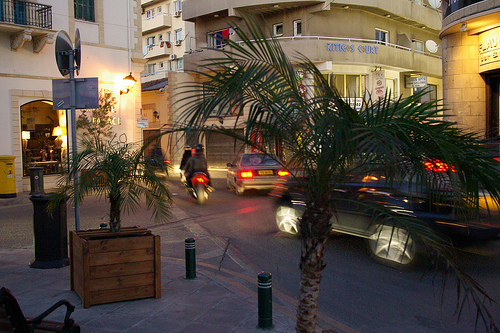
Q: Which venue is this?
A: This is a road.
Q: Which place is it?
A: It is a road.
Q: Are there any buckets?
A: No, there are no buckets.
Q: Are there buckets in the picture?
A: No, there are no buckets.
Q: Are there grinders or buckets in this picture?
A: No, there are no buckets or grinders.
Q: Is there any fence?
A: No, there are no fences.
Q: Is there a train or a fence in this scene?
A: No, there are no fences or trains.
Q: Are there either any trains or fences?
A: No, there are no fences or trains.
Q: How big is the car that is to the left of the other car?
A: The car is small.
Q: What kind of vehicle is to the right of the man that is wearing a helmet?
A: The vehicle is a car.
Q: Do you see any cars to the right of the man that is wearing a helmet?
A: Yes, there is a car to the right of the man.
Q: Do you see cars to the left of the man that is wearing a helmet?
A: No, the car is to the right of the man.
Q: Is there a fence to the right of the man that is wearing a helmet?
A: No, there is a car to the right of the man.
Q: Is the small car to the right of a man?
A: Yes, the car is to the right of a man.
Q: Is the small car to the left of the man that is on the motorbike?
A: No, the car is to the right of the man.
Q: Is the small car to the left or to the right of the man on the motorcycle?
A: The car is to the right of the man.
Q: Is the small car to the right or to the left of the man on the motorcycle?
A: The car is to the right of the man.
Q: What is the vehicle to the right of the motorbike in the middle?
A: The vehicle is a car.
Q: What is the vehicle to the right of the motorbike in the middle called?
A: The vehicle is a car.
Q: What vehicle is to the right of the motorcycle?
A: The vehicle is a car.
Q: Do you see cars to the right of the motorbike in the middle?
A: Yes, there is a car to the right of the motorcycle.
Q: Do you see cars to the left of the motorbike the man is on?
A: No, the car is to the right of the motorcycle.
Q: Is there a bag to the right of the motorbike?
A: No, there is a car to the right of the motorbike.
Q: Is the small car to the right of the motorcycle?
A: Yes, the car is to the right of the motorcycle.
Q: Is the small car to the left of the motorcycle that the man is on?
A: No, the car is to the right of the motorcycle.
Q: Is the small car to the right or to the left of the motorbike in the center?
A: The car is to the right of the motorcycle.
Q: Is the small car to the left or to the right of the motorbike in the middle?
A: The car is to the right of the motorcycle.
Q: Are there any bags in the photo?
A: No, there are no bags.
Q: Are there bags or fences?
A: No, there are no bags or fences.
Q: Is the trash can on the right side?
A: No, the trash can is on the left of the image.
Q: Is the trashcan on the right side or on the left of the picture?
A: The trashcan is on the left of the image.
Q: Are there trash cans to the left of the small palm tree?
A: Yes, there is a trash can to the left of the palm.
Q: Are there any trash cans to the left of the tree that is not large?
A: Yes, there is a trash can to the left of the palm.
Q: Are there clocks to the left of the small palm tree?
A: No, there is a trash can to the left of the palm tree.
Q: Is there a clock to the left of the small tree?
A: No, there is a trash can to the left of the palm tree.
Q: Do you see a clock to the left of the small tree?
A: No, there is a trash can to the left of the palm tree.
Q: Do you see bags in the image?
A: No, there are no bags.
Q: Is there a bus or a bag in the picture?
A: No, there are no bags or buses.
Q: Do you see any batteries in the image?
A: No, there are no batteries.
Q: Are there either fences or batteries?
A: No, there are no batteries or fences.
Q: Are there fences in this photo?
A: No, there are no fences.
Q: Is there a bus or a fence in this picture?
A: No, there are no fences or buses.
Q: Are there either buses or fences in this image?
A: No, there are no fences or buses.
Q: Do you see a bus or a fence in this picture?
A: No, there are no fences or buses.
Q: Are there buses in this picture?
A: No, there are no buses.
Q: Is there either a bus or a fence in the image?
A: No, there are no buses or fences.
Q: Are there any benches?
A: Yes, there is a bench.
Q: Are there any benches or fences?
A: Yes, there is a bench.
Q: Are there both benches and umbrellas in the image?
A: No, there is a bench but no umbrellas.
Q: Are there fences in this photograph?
A: No, there are no fences.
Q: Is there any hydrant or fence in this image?
A: No, there are no fences or fire hydrants.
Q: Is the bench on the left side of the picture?
A: Yes, the bench is on the left of the image.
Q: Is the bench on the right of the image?
A: No, the bench is on the left of the image.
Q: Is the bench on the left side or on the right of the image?
A: The bench is on the left of the image.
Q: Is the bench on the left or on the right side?
A: The bench is on the left of the image.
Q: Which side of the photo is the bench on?
A: The bench is on the left of the image.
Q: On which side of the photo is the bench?
A: The bench is on the left of the image.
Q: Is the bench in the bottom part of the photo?
A: Yes, the bench is in the bottom of the image.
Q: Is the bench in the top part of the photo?
A: No, the bench is in the bottom of the image.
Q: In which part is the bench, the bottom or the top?
A: The bench is in the bottom of the image.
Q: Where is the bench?
A: The bench is on the sidewalk.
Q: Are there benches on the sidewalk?
A: Yes, there is a bench on the sidewalk.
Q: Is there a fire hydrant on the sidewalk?
A: No, there is a bench on the sidewalk.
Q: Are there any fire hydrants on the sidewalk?
A: No, there is a bench on the sidewalk.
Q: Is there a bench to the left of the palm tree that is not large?
A: Yes, there is a bench to the left of the palm.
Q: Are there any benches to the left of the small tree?
A: Yes, there is a bench to the left of the palm.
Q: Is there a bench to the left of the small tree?
A: Yes, there is a bench to the left of the palm.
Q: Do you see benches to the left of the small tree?
A: Yes, there is a bench to the left of the palm.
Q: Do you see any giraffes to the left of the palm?
A: No, there is a bench to the left of the palm.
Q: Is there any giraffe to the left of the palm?
A: No, there is a bench to the left of the palm.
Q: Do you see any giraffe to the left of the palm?
A: No, there is a bench to the left of the palm.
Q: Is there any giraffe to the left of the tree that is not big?
A: No, there is a bench to the left of the palm.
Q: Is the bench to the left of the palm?
A: Yes, the bench is to the left of the palm.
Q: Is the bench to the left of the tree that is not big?
A: Yes, the bench is to the left of the palm.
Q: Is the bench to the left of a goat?
A: No, the bench is to the left of the palm.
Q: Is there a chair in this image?
A: No, there are no chairs.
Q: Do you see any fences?
A: No, there are no fences.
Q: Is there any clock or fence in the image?
A: No, there are no fences or clocks.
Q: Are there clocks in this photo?
A: No, there are no clocks.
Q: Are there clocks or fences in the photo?
A: No, there are no clocks or fences.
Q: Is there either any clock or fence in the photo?
A: No, there are no clocks or fences.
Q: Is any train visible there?
A: No, there are no trains.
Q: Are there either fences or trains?
A: No, there are no trains or fences.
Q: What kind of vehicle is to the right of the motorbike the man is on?
A: The vehicle is a car.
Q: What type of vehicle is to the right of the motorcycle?
A: The vehicle is a car.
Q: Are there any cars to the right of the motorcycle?
A: Yes, there is a car to the right of the motorcycle.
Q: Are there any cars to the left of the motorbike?
A: No, the car is to the right of the motorbike.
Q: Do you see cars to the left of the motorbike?
A: No, the car is to the right of the motorbike.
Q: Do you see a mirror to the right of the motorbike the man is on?
A: No, there is a car to the right of the motorcycle.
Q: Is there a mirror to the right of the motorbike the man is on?
A: No, there is a car to the right of the motorcycle.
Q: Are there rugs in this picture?
A: No, there are no rugs.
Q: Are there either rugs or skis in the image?
A: No, there are no rugs or skis.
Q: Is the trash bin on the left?
A: Yes, the trash bin is on the left of the image.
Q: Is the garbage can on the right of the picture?
A: No, the garbage can is on the left of the image.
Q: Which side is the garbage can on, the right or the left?
A: The garbage can is on the left of the image.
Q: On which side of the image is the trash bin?
A: The trash bin is on the left of the image.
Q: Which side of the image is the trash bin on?
A: The trash bin is on the left of the image.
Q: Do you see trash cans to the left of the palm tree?
A: Yes, there is a trash can to the left of the palm tree.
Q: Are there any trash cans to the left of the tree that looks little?
A: Yes, there is a trash can to the left of the palm tree.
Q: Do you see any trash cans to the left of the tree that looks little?
A: Yes, there is a trash can to the left of the palm tree.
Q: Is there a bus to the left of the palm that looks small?
A: No, there is a trash can to the left of the palm tree.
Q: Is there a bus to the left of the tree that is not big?
A: No, there is a trash can to the left of the palm tree.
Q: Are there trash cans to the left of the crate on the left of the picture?
A: Yes, there is a trash can to the left of the crate.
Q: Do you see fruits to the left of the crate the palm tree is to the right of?
A: No, there is a trash can to the left of the crate.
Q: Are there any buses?
A: No, there are no buses.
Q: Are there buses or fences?
A: No, there are no buses or fences.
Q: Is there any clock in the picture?
A: No, there are no clocks.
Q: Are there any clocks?
A: No, there are no clocks.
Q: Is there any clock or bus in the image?
A: No, there are no clocks or buses.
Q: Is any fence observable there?
A: No, there are no fences.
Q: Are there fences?
A: No, there are no fences.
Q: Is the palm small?
A: Yes, the palm is small.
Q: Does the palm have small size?
A: Yes, the palm is small.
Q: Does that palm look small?
A: Yes, the palm is small.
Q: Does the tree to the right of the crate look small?
A: Yes, the palm is small.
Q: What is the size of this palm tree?
A: The palm tree is small.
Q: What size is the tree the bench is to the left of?
A: The palm tree is small.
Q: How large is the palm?
A: The palm is small.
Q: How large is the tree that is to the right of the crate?
A: The palm is small.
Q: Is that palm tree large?
A: No, the palm tree is small.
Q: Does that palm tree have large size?
A: No, the palm tree is small.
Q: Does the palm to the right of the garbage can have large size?
A: No, the palm is small.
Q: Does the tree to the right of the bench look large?
A: No, the palm is small.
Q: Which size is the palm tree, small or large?
A: The palm tree is small.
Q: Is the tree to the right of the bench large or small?
A: The palm tree is small.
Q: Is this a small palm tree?
A: Yes, this is a small palm tree.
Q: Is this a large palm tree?
A: No, this is a small palm tree.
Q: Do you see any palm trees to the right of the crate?
A: Yes, there is a palm tree to the right of the crate.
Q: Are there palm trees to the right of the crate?
A: Yes, there is a palm tree to the right of the crate.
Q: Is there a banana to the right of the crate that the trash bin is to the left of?
A: No, there is a palm tree to the right of the crate.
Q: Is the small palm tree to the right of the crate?
A: Yes, the palm is to the right of the crate.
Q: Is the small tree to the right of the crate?
A: Yes, the palm is to the right of the crate.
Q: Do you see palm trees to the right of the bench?
A: Yes, there is a palm tree to the right of the bench.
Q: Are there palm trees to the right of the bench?
A: Yes, there is a palm tree to the right of the bench.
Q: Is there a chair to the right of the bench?
A: No, there is a palm tree to the right of the bench.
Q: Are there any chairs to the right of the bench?
A: No, there is a palm tree to the right of the bench.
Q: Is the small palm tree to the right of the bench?
A: Yes, the palm is to the right of the bench.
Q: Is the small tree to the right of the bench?
A: Yes, the palm is to the right of the bench.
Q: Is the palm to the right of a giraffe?
A: No, the palm is to the right of the bench.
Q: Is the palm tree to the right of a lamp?
A: No, the palm tree is to the right of the garbage can.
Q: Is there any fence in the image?
A: No, there are no fences.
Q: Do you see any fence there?
A: No, there are no fences.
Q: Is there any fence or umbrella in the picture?
A: No, there are no fences or umbrellas.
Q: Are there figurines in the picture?
A: No, there are no figurines.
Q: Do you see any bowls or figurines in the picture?
A: No, there are no figurines or bowls.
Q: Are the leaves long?
A: Yes, the leaves are long.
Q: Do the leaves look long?
A: Yes, the leaves are long.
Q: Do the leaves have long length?
A: Yes, the leaves are long.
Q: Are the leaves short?
A: No, the leaves are long.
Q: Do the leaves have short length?
A: No, the leaves are long.